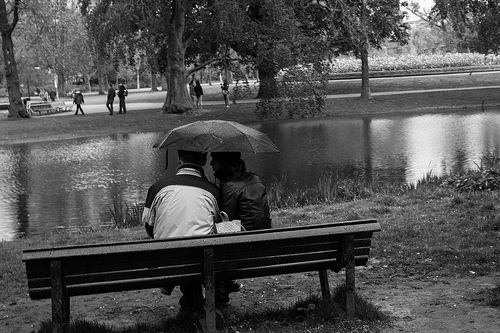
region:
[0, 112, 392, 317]
Two people sitting together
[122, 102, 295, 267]
Sitting together under an umbrella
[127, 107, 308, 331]
Sitting on a park bench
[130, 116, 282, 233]
Couple sitting under umbrella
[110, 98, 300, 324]
Couple on park bench and under an umbrella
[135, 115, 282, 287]
Couple talking under an umbrella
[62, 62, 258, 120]
People across the pond standing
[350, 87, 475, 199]
Small pond at a park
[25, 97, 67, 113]
Empty park benches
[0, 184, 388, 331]
Park bench with two people on it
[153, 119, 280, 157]
a dark colored umbrella canopy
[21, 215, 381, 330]
a wooden park bench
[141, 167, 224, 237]
a man wearing a two tone jacket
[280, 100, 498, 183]
a small pond in the park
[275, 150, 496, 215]
tall grass growing on the river bank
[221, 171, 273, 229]
someone sitting on the bench wearing a solid color jacket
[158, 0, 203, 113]
a huge tree across the pond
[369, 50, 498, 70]
a field of flowers across the pond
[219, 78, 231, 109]
a girl taking a picture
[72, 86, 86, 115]
someone walking on the other side of the pond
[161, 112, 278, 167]
the umbrella is black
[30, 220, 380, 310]
the bench is wet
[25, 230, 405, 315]
the bench is wooden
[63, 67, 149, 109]
people are in the background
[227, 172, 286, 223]
the jacket is black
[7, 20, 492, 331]
the weather is rainy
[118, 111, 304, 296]
they are in a park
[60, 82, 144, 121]
they are walking in a park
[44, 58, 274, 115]
they are five people in the park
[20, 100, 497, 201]
the water is in the park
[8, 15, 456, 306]
two people sitting on park bench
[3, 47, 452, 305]
two people on park bench under umbrella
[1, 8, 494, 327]
two people sitting by water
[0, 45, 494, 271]
light reflecting off of water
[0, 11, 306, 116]
multiple people walking in park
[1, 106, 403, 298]
one person looking at the other on park bench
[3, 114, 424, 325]
bag sitting between two people on bench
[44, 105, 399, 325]
rain glistening off of umbrella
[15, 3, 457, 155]
leafy tree in background bordering lake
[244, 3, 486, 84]
leafy vegetation in background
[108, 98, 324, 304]
Couple sitting on a bench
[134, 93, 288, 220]
They are sharing an umbrella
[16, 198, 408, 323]
The bench is long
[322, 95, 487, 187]
the pond water is calm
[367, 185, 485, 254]
Short grass surrounding the pond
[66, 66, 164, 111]
People walking down the path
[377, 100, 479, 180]
reflection of light in the pond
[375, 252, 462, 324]
Grass has dirt patches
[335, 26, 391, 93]
Tree trunk on other side of pond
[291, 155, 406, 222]
Long grass growing beside pond